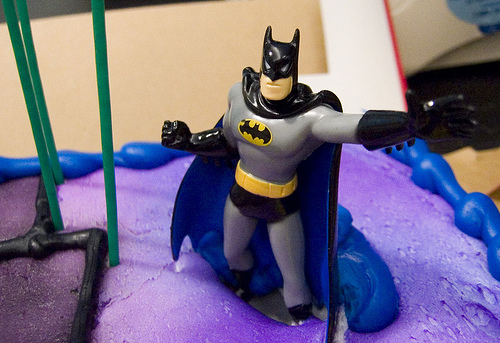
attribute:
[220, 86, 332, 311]
suit — gray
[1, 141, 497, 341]
icing — purple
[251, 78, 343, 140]
cape — black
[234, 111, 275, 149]
logo — yellow and black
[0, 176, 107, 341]
icing — black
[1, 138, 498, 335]
cake — purple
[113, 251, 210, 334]
icing — purple buttercream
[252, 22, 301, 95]
face mask — black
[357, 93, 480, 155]
glove — black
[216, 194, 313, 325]
legs — grey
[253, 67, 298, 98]
mask — black